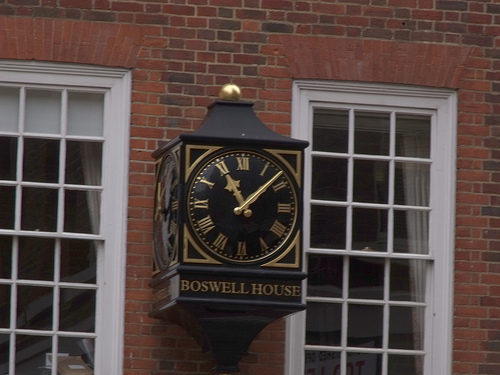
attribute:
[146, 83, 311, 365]
clock — black, 11:08 time, gold, ornate, saying 11:08, square, decorative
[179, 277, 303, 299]
boswell house — gold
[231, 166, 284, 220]
hand — gold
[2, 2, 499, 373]
wall — red, bricked, brick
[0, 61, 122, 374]
window pane — white, wood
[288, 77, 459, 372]
window pane — white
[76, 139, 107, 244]
curtain — beige, white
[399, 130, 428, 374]
curtain — beige, white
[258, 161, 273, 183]
number i — roman numeral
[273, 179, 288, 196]
number ii — roman numeral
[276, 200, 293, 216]
number iii — roman numeral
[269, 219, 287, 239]
number iiii — roman numeral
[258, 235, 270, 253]
number v — roman numeral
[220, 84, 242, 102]
ball — gold, decorative